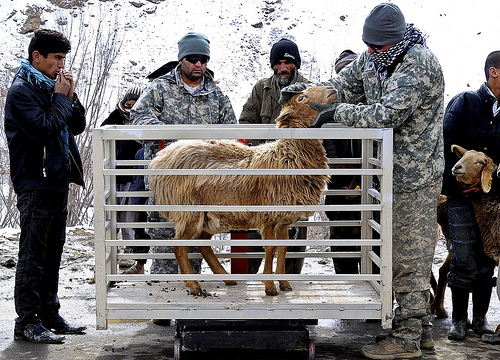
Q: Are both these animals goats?
A: Yes, all the animals are goats.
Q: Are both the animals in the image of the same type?
A: Yes, all the animals are goats.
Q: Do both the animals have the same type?
A: Yes, all the animals are goats.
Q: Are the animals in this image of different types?
A: No, all the animals are goats.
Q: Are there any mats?
A: No, there are no mats.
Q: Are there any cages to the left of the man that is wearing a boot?
A: Yes, there is a cage to the left of the man.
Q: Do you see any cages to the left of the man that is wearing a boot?
A: Yes, there is a cage to the left of the man.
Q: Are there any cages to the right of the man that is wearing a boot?
A: No, the cage is to the left of the man.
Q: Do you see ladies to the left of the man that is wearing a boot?
A: No, there is a cage to the left of the man.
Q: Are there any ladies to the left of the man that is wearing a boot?
A: No, there is a cage to the left of the man.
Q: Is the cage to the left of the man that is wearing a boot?
A: Yes, the cage is to the left of the man.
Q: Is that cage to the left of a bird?
A: No, the cage is to the left of the man.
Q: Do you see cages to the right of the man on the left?
A: Yes, there is a cage to the right of the man.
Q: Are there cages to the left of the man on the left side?
A: No, the cage is to the right of the man.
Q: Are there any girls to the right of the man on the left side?
A: No, there is a cage to the right of the man.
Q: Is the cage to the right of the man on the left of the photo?
A: Yes, the cage is to the right of the man.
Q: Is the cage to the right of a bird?
A: No, the cage is to the right of the man.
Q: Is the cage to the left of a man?
A: No, the cage is to the right of a man.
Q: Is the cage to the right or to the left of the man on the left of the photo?
A: The cage is to the right of the man.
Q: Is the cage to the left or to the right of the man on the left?
A: The cage is to the right of the man.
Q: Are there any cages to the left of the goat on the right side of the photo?
A: Yes, there is a cage to the left of the goat.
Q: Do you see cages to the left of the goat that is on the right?
A: Yes, there is a cage to the left of the goat.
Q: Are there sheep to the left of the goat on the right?
A: No, there is a cage to the left of the goat.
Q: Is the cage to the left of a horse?
A: No, the cage is to the left of the goat.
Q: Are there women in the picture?
A: No, there are no women.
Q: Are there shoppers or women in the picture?
A: No, there are no women or shoppers.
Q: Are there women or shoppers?
A: No, there are no women or shoppers.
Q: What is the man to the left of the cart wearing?
A: The man is wearing a shoe.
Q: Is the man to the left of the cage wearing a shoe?
A: Yes, the man is wearing a shoe.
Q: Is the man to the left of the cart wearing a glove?
A: No, the man is wearing a shoe.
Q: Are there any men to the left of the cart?
A: Yes, there is a man to the left of the cart.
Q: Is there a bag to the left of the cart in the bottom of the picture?
A: No, there is a man to the left of the cart.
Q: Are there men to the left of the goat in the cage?
A: Yes, there is a man to the left of the goat.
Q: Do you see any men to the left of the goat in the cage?
A: Yes, there is a man to the left of the goat.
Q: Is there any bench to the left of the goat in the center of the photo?
A: No, there is a man to the left of the goat.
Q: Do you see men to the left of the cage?
A: Yes, there is a man to the left of the cage.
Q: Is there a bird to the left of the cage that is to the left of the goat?
A: No, there is a man to the left of the cage.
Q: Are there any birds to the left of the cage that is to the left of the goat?
A: No, there is a man to the left of the cage.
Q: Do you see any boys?
A: No, there are no boys.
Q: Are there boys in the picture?
A: No, there are no boys.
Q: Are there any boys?
A: No, there are no boys.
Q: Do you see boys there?
A: No, there are no boys.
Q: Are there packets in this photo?
A: No, there are no packets.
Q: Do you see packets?
A: No, there are no packets.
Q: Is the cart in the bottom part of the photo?
A: Yes, the cart is in the bottom of the image.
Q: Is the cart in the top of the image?
A: No, the cart is in the bottom of the image.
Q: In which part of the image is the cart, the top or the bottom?
A: The cart is in the bottom of the image.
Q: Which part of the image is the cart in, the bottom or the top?
A: The cart is in the bottom of the image.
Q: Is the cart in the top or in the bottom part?
A: The cart is in the bottom of the image.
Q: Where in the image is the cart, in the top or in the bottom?
A: The cart is in the bottom of the image.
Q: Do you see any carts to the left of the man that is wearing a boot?
A: Yes, there is a cart to the left of the man.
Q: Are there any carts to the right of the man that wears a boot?
A: No, the cart is to the left of the man.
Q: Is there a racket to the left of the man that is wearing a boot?
A: No, there is a cart to the left of the man.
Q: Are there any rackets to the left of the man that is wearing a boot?
A: No, there is a cart to the left of the man.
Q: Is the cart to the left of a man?
A: Yes, the cart is to the left of a man.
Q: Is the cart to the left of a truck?
A: No, the cart is to the left of a man.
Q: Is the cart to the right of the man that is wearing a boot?
A: No, the cart is to the left of the man.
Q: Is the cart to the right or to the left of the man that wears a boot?
A: The cart is to the left of the man.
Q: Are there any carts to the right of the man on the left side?
A: Yes, there is a cart to the right of the man.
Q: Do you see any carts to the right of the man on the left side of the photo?
A: Yes, there is a cart to the right of the man.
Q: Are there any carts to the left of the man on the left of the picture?
A: No, the cart is to the right of the man.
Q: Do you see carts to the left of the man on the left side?
A: No, the cart is to the right of the man.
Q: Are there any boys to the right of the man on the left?
A: No, there is a cart to the right of the man.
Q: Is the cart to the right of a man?
A: Yes, the cart is to the right of a man.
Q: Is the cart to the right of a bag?
A: No, the cart is to the right of a man.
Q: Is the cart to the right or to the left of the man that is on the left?
A: The cart is to the right of the man.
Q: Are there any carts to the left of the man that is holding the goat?
A: Yes, there is a cart to the left of the man.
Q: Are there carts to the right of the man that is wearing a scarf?
A: No, the cart is to the left of the man.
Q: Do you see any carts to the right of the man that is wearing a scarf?
A: No, the cart is to the left of the man.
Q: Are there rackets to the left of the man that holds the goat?
A: No, there is a cart to the left of the man.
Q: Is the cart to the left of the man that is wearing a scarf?
A: Yes, the cart is to the left of the man.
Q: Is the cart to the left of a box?
A: No, the cart is to the left of the man.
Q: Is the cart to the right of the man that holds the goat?
A: No, the cart is to the left of the man.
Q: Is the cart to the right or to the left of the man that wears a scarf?
A: The cart is to the left of the man.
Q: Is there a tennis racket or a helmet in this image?
A: No, there are no helmets or rackets.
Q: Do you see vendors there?
A: No, there are no vendors.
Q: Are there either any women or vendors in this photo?
A: No, there are no vendors or women.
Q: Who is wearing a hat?
A: The man is wearing a hat.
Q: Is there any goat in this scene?
A: Yes, there is a goat.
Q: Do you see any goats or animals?
A: Yes, there is a goat.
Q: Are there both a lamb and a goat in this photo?
A: No, there is a goat but no lambs.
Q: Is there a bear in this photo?
A: No, there are no bears.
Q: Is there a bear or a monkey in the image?
A: No, there are no bears or monkeys.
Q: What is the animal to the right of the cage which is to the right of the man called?
A: The animal is a goat.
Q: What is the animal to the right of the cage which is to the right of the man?
A: The animal is a goat.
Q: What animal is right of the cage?
A: The animal is a goat.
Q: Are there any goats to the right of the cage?
A: Yes, there is a goat to the right of the cage.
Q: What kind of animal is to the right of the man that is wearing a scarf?
A: The animal is a goat.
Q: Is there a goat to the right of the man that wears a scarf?
A: Yes, there is a goat to the right of the man.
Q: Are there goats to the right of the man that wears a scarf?
A: Yes, there is a goat to the right of the man.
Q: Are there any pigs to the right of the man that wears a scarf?
A: No, there is a goat to the right of the man.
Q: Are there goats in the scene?
A: Yes, there is a goat.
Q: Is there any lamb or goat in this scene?
A: Yes, there is a goat.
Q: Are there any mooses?
A: No, there are no mooses.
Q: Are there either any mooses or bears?
A: No, there are no mooses or bears.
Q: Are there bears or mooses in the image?
A: No, there are no mooses or bears.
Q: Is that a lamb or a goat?
A: That is a goat.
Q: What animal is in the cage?
A: The goat is in the cage.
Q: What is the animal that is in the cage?
A: The animal is a goat.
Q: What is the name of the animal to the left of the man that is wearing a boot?
A: The animal is a goat.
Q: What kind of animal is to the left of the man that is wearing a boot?
A: The animal is a goat.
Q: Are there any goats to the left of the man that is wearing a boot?
A: Yes, there is a goat to the left of the man.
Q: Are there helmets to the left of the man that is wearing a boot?
A: No, there is a goat to the left of the man.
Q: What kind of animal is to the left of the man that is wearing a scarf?
A: The animal is a goat.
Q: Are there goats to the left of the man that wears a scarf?
A: Yes, there is a goat to the left of the man.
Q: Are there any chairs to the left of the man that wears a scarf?
A: No, there is a goat to the left of the man.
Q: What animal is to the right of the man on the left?
A: The animal is a goat.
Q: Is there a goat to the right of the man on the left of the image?
A: Yes, there is a goat to the right of the man.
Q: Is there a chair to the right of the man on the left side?
A: No, there is a goat to the right of the man.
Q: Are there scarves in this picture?
A: Yes, there is a scarf.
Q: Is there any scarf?
A: Yes, there is a scarf.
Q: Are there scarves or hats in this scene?
A: Yes, there is a scarf.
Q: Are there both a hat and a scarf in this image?
A: Yes, there are both a scarf and a hat.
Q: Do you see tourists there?
A: No, there are no tourists.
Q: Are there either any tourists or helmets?
A: No, there are no tourists or helmets.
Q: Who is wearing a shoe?
A: The man is wearing a shoe.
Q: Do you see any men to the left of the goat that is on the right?
A: Yes, there is a man to the left of the goat.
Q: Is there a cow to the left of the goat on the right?
A: No, there is a man to the left of the goat.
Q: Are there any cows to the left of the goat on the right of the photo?
A: No, there is a man to the left of the goat.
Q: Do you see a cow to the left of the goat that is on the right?
A: No, there is a man to the left of the goat.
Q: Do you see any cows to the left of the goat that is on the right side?
A: No, there is a man to the left of the goat.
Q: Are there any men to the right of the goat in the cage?
A: Yes, there is a man to the right of the goat.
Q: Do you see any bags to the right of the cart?
A: No, there is a man to the right of the cart.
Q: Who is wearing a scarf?
A: The man is wearing a scarf.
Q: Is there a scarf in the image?
A: Yes, there is a scarf.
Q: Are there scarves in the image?
A: Yes, there is a scarf.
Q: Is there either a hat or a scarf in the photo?
A: Yes, there is a scarf.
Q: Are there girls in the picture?
A: No, there are no girls.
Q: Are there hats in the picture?
A: Yes, there is a hat.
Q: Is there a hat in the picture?
A: Yes, there is a hat.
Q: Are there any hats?
A: Yes, there is a hat.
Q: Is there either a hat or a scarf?
A: Yes, there is a hat.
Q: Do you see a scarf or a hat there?
A: Yes, there is a hat.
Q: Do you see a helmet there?
A: No, there are no helmets.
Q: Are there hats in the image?
A: Yes, there is a hat.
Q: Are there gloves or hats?
A: Yes, there is a hat.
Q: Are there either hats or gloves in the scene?
A: Yes, there is a hat.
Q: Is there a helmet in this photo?
A: No, there are no helmets.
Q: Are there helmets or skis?
A: No, there are no helmets or skis.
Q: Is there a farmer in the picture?
A: No, there are no farmers.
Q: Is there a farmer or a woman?
A: No, there are no farmers or women.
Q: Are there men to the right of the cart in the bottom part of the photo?
A: Yes, there is a man to the right of the cart.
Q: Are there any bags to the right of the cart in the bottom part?
A: No, there is a man to the right of the cart.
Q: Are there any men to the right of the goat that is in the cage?
A: Yes, there is a man to the right of the goat.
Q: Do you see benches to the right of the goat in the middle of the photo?
A: No, there is a man to the right of the goat.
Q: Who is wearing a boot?
A: The man is wearing a boot.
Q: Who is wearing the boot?
A: The man is wearing a boot.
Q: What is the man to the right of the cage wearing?
A: The man is wearing a boot.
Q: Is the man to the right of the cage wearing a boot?
A: Yes, the man is wearing a boot.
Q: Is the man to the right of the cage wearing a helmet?
A: No, the man is wearing a boot.